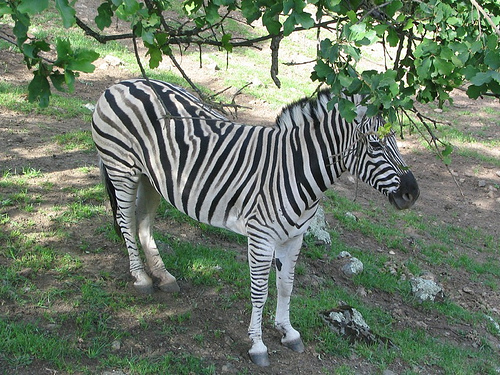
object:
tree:
[235, 9, 324, 71]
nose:
[383, 170, 428, 215]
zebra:
[88, 87, 420, 339]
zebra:
[91, 67, 420, 364]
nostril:
[380, 177, 424, 212]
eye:
[370, 136, 387, 152]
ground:
[444, 153, 466, 173]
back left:
[159, 279, 179, 291]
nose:
[383, 186, 424, 218]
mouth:
[387, 172, 420, 215]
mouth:
[391, 193, 406, 212]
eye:
[365, 132, 391, 158]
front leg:
[273, 232, 310, 354]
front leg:
[245, 232, 273, 369]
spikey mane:
[254, 77, 329, 143]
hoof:
[281, 337, 308, 357]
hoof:
[244, 352, 271, 366]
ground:
[388, 108, 447, 188]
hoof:
[131, 281, 155, 294]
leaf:
[337, 97, 357, 121]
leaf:
[342, 22, 363, 42]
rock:
[411, 270, 448, 305]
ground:
[0, 0, 500, 374]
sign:
[0, 0, 496, 153]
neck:
[289, 115, 345, 208]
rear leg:
[136, 176, 181, 295]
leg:
[242, 223, 274, 370]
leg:
[268, 236, 307, 356]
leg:
[100, 167, 151, 296]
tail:
[100, 159, 124, 241]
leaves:
[1, 1, 498, 161]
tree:
[4, 0, 498, 187]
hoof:
[158, 269, 181, 293]